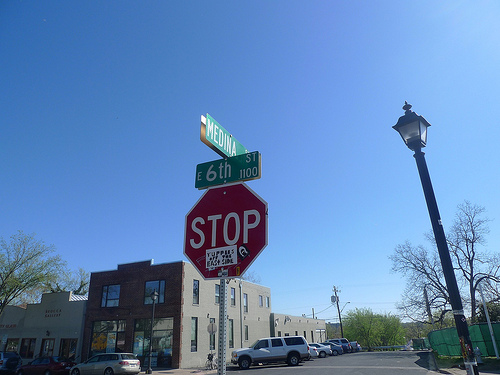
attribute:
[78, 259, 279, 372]
building — brick, red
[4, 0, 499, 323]
sky — blue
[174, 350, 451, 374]
road — grey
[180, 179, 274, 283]
sign — white, red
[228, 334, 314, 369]
truck — parked, white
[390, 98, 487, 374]
light pole — black, tall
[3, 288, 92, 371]
store — white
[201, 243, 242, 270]
sticker — black, white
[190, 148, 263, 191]
sign — green, white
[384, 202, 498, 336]
tree — brown, green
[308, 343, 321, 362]
vehicle — white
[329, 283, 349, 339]
post — brown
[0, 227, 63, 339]
tree — large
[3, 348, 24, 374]
suv — white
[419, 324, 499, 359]
fence — green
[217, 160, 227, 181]
letter — white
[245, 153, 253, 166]
letter — white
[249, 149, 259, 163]
letter — white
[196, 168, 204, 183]
letter — white